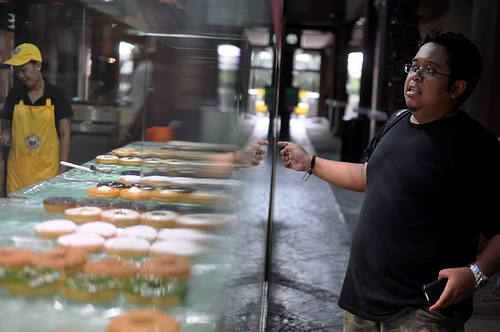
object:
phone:
[418, 276, 449, 310]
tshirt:
[337, 110, 500, 322]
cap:
[4, 41, 44, 67]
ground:
[279, 145, 379, 248]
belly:
[347, 183, 476, 278]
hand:
[274, 140, 309, 173]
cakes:
[32, 218, 76, 239]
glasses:
[403, 64, 452, 79]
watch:
[467, 263, 490, 293]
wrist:
[460, 262, 487, 291]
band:
[308, 148, 318, 176]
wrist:
[305, 152, 320, 176]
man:
[275, 31, 500, 332]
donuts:
[106, 308, 185, 332]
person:
[0, 43, 75, 198]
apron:
[4, 99, 63, 199]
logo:
[23, 134, 42, 152]